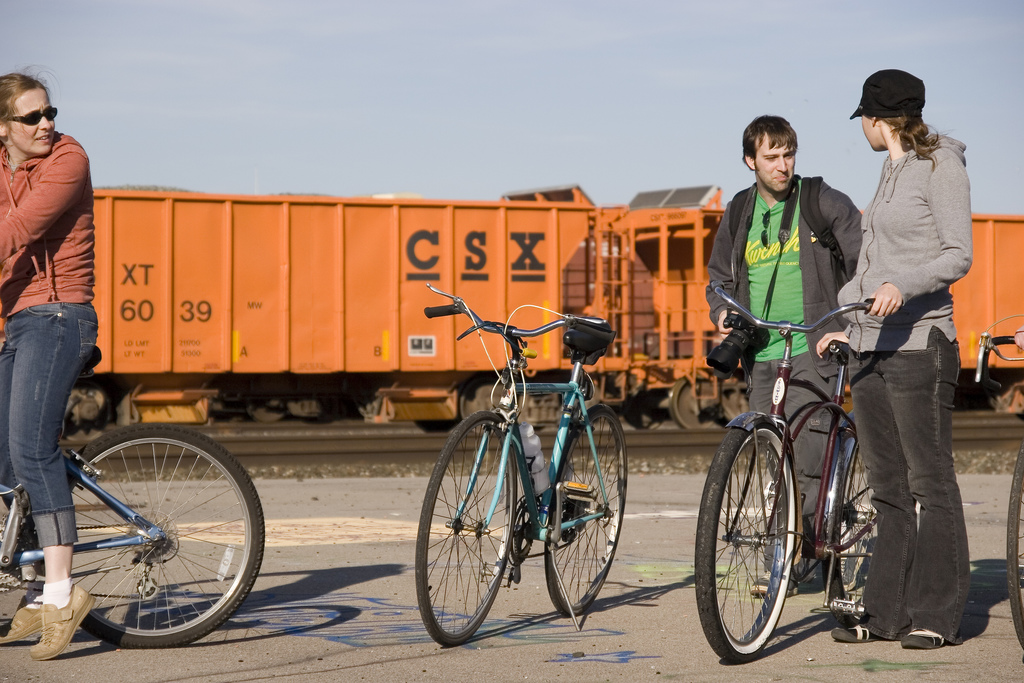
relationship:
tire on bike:
[66, 419, 266, 647] [1, 340, 265, 650]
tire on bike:
[411, 408, 519, 643] [414, 275, 631, 648]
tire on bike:
[543, 396, 630, 618] [414, 275, 631, 648]